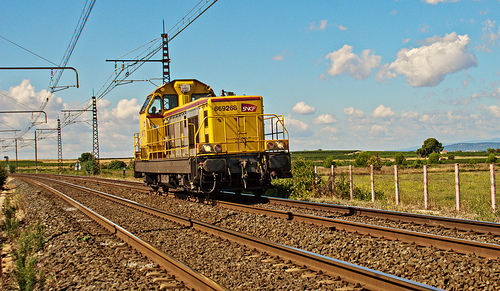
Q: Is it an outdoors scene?
A: Yes, it is outdoors.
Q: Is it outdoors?
A: Yes, it is outdoors.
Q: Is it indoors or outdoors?
A: It is outdoors.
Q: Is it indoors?
A: No, it is outdoors.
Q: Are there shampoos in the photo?
A: No, there are no shampoos.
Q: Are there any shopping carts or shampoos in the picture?
A: No, there are no shampoos or shopping carts.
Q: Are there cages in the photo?
A: No, there are no cages.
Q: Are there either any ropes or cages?
A: No, there are no cages or ropes.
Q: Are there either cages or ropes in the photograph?
A: No, there are no cages or ropes.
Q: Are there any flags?
A: No, there are no flags.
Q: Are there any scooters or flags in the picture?
A: No, there are no flags or scooters.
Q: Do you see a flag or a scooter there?
A: No, there are no flags or scooters.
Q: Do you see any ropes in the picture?
A: No, there are no ropes.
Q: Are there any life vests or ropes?
A: No, there are no ropes or life vests.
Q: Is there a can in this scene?
A: No, there are no cans.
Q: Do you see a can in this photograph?
A: No, there are no cans.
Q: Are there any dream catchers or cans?
A: No, there are no cans or dream catchers.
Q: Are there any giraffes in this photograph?
A: No, there are no giraffes.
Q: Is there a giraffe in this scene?
A: No, there are no giraffes.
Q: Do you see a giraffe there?
A: No, there are no giraffes.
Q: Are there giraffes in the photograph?
A: No, there are no giraffes.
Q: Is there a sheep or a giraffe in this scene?
A: No, there are no giraffes or sheep.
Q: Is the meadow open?
A: Yes, the meadow is open.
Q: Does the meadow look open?
A: Yes, the meadow is open.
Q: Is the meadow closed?
A: No, the meadow is open.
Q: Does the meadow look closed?
A: No, the meadow is open.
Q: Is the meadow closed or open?
A: The meadow is open.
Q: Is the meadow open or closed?
A: The meadow is open.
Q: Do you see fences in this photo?
A: Yes, there is a fence.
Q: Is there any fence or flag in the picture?
A: Yes, there is a fence.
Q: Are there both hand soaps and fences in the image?
A: No, there is a fence but no hand soaps.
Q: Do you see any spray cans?
A: No, there are no spray cans.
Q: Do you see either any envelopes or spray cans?
A: No, there are no spray cans or envelopes.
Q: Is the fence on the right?
A: Yes, the fence is on the right of the image.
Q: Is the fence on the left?
A: No, the fence is on the right of the image.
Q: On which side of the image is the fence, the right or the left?
A: The fence is on the right of the image.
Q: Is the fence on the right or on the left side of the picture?
A: The fence is on the right of the image.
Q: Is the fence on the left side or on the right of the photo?
A: The fence is on the right of the image.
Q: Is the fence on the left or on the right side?
A: The fence is on the right of the image.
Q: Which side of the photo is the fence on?
A: The fence is on the right of the image.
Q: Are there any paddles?
A: No, there are no paddles.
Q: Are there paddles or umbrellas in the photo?
A: No, there are no paddles or umbrellas.